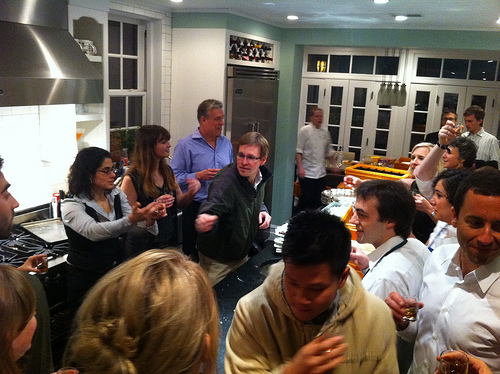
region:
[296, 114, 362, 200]
man wearing a white shirt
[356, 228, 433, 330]
man wearing a white shirt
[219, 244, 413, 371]
man wearing a hoodie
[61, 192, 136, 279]
woman wearing a black vest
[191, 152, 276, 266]
man wearing a jacket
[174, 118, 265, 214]
man wearing a blue shirt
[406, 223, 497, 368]
man wearing a white shirt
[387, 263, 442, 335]
man holding a drink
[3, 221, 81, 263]
black kitchen stove top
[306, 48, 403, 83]
series of windows above door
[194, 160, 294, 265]
the jacket is black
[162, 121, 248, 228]
the shirt is purple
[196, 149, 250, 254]
A man is extending his arm.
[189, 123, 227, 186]
a man is wearing a blue shirt.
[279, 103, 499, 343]
A group of people are inside a kitchen.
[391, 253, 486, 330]
A man is holding a glass.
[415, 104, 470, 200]
A person is raising their hand.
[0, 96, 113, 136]
A light is shining above a stove.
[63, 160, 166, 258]
a woman is standing in front of a stove.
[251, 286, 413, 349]
A man is wearing a tan hoodie.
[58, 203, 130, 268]
A woman is wearing a black vest.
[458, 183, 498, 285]
A man is attentive to someone.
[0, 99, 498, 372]
the people in the kitchen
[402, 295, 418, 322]
the shot glass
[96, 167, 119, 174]
the woman's glasses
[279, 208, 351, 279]
the hair on the man's head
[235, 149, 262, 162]
the man's glasses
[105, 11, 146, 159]
the window in the kitchen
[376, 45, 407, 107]
the lights hanging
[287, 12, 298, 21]
the light in the ceiling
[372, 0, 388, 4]
the light in the ceiling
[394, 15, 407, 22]
the light in the ceiling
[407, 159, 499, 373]
Man wearing a white shirt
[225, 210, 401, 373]
Man wearing a brown hoodie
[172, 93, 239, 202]
Man where a blue shirt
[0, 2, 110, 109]
Hood over the stove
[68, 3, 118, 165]
Shelves next to the stove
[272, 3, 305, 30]
Lignt in th ceiling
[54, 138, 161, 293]
Lady wearing a black dress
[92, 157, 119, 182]
Glasses on woman's face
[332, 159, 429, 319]
Man wearing a white shirt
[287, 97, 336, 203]
Man standing near the doors